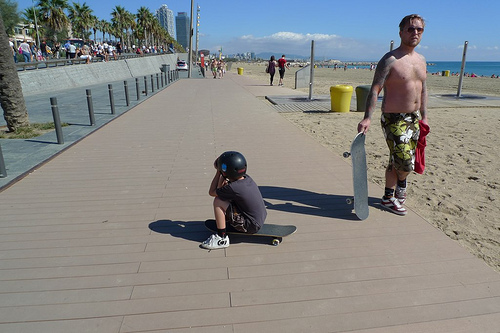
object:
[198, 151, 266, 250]
boy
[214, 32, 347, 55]
cloud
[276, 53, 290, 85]
person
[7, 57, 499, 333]
boardwalk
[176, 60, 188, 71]
car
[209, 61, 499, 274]
beach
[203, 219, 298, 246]
skateboard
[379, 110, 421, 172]
shorts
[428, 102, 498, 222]
sand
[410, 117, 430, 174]
shirt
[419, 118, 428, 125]
hand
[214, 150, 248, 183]
helmet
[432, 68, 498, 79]
people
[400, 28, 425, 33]
sunglasses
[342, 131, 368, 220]
skateboard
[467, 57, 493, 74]
water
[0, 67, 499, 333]
walk way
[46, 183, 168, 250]
wood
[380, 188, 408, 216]
shoes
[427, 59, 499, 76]
ocean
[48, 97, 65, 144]
pole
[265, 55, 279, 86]
person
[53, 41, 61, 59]
person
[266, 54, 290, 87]
couple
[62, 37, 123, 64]
people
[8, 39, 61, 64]
people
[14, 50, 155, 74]
road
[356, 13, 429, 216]
man